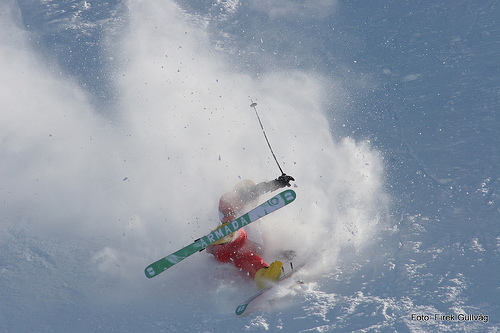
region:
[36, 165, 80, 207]
splash of a snow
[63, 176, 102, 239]
splash of a snow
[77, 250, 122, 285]
splash of a snow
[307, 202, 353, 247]
splash of a snow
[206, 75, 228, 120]
splash of a snow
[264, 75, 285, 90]
splash of a snow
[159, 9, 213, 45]
splash of a snow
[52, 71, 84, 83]
splash of a snow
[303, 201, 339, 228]
splash of a snow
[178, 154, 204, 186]
splash of a snow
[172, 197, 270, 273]
this is a man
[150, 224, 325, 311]
the man is a skier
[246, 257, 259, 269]
these are some pants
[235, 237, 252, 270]
the pants are red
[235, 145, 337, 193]
this is a pole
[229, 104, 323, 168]
the pole is metal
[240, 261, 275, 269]
this is a shoe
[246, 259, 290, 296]
the shoe is yellow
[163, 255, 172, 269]
this is a ski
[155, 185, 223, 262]
the ski is green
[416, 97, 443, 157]
snow on a field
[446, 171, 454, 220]
snow on a field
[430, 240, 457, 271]
snow on a field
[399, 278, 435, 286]
snow on a field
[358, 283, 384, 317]
snow on a field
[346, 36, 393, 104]
snow on a field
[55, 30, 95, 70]
snow on a field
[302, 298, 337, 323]
snow on a field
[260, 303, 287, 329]
snow on a field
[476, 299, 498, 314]
snow on a field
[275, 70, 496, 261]
ground covered in snow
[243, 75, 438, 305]
ground covered in white snow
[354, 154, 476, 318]
snow covering the ground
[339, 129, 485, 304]
white snow covering the ground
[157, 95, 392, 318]
a person that is skiing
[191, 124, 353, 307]
a person that is skiing on the snow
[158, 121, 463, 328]
a person skiin gon the white snow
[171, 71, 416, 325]
a p erson skiing outside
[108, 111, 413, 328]
a person on skies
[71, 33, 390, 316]
a person holding ski poles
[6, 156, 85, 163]
Glass of red wine in someone's hand.Glass of red wine in someone's hand.